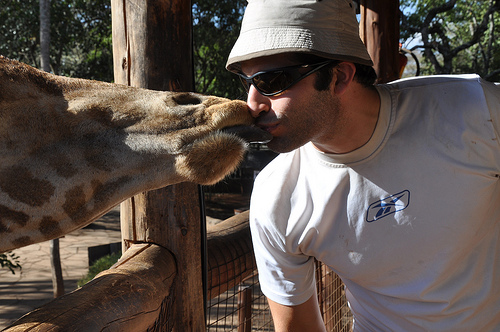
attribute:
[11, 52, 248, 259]
cup — brown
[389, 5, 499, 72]
tree — green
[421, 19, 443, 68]
branches — curved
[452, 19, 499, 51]
branches — curved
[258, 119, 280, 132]
mouth — man's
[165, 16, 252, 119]
foliage — green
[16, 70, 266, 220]
giraffe — giraffe's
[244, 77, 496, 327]
shirt — white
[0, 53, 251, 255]
giraffe — brown, tan, licking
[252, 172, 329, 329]
arm — man's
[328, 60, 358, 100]
ear — man's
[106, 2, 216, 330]
post — wooden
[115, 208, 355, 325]
fence — wooden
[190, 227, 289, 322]
wooden fence — black, metal, mesh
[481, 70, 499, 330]
shirt — white, tee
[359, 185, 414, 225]
logo — black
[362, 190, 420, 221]
reebok sign — blue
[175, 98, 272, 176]
mouth — giraffe's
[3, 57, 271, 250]
giraffe — tan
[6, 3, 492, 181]
foliage — green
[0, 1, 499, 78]
sky — blue